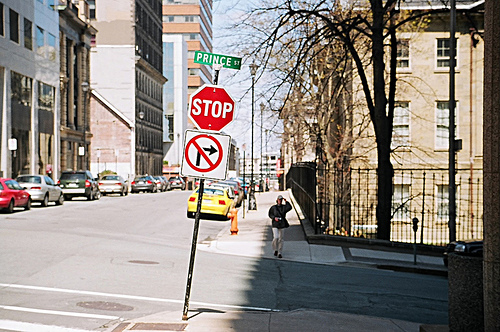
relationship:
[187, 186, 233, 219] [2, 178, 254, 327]
car on street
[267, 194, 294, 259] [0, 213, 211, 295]
pedestrian near intersection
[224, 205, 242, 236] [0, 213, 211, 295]
fire hydrant near intersection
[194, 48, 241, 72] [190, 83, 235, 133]
sign above sign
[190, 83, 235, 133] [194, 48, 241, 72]
sign below sign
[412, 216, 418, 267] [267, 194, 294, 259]
meter near pedestrian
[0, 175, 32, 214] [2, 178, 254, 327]
car on street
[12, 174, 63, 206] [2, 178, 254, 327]
car on street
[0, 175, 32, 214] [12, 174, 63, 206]
car behind car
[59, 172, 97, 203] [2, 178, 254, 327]
car on street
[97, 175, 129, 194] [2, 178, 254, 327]
car on street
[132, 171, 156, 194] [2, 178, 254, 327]
car on street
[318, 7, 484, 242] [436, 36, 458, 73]
building has window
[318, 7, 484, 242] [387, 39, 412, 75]
building has window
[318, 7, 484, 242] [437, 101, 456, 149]
building has window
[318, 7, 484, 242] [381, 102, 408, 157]
building has window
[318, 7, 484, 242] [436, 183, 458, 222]
building has window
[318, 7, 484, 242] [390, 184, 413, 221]
building has window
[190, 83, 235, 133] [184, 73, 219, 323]
sign on pole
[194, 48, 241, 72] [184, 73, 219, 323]
sign on pole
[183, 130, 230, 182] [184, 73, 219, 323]
sign on pole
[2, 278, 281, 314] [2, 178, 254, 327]
line on street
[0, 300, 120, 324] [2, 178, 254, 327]
line on street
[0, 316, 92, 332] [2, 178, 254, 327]
line on street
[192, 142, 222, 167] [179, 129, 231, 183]
right turns on sign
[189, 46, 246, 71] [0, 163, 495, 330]
sign on ground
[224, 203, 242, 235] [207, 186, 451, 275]
fire hydrant on sidewalk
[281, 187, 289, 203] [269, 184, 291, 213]
hand near head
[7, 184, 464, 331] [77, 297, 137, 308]
asphalt with drain cover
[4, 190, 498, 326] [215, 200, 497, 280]
street with curb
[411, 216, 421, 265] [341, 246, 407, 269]
meter on sidewalk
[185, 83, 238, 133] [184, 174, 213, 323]
sign on pole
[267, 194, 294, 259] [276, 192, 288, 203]
pedestrian with hat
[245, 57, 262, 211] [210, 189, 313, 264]
street light on sidewalk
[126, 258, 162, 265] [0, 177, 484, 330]
drain cover in street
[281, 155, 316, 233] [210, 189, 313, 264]
fence near sidewalk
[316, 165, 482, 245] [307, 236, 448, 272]
fence near sidewalk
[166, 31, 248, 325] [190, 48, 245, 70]
leaning pole with sign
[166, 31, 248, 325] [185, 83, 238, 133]
leaning pole with sign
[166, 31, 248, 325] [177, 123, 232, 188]
leaning pole with turn sign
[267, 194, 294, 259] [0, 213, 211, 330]
pedestrian approaching intersection